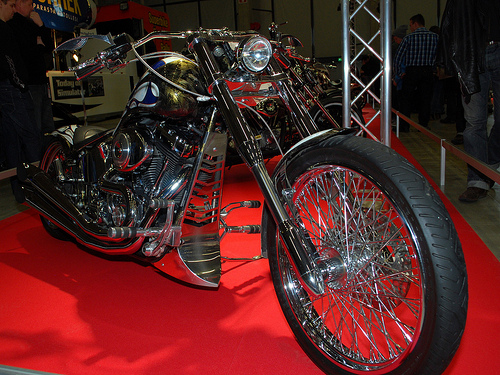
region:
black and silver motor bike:
[21, 31, 461, 374]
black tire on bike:
[270, 137, 469, 373]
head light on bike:
[241, 35, 271, 73]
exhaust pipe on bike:
[13, 163, 155, 262]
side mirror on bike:
[53, 34, 89, 59]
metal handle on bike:
[73, 48, 123, 79]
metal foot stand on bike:
[109, 226, 162, 239]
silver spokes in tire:
[295, 173, 420, 360]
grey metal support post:
[339, 2, 391, 148]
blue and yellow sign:
[37, 1, 91, 31]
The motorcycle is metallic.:
[16, 25, 468, 374]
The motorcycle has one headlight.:
[18, 8, 465, 373]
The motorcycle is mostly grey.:
[20, 17, 467, 374]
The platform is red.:
[0, 95, 499, 372]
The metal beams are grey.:
[343, 0, 392, 165]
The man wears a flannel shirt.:
[391, 12, 438, 134]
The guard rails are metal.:
[360, 81, 499, 253]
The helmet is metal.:
[120, 53, 208, 122]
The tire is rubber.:
[268, 118, 467, 374]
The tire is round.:
[256, 129, 471, 373]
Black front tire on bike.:
[319, 146, 441, 331]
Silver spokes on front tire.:
[306, 188, 401, 330]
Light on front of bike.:
[233, 44, 275, 72]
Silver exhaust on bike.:
[28, 180, 93, 235]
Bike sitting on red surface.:
[23, 264, 286, 374]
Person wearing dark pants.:
[455, 98, 488, 160]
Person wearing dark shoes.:
[451, 179, 493, 216]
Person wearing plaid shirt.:
[408, 28, 439, 55]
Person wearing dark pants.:
[393, 68, 446, 111]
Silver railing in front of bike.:
[398, 108, 463, 162]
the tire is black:
[269, 133, 465, 373]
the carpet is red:
[0, 110, 498, 374]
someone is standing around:
[398, 14, 437, 136]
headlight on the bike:
[241, 38, 270, 70]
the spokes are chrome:
[275, 165, 422, 370]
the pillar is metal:
[341, 1, 389, 148]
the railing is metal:
[388, 110, 498, 257]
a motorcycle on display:
[20, 24, 468, 374]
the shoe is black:
[458, 185, 488, 203]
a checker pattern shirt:
[395, 28, 435, 66]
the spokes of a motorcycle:
[331, 193, 390, 318]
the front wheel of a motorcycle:
[259, 138, 473, 373]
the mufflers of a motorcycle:
[12, 165, 132, 259]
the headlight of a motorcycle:
[224, 28, 272, 77]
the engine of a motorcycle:
[104, 120, 190, 222]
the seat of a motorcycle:
[66, 112, 116, 152]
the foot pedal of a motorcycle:
[98, 215, 152, 252]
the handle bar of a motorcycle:
[59, 30, 191, 78]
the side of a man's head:
[404, 10, 430, 34]